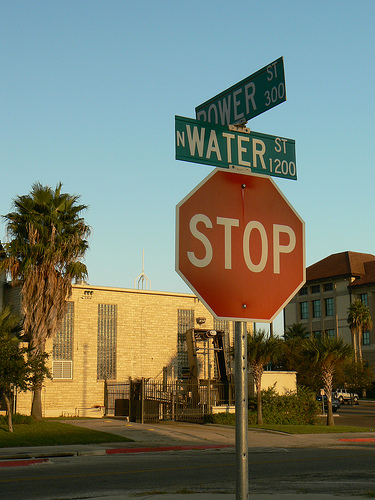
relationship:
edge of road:
[4, 490, 373, 500] [1, 439, 375, 495]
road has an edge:
[1, 439, 375, 495] [4, 490, 373, 500]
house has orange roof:
[279, 247, 374, 398] [304, 251, 374, 285]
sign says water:
[175, 115, 299, 182] [184, 123, 268, 168]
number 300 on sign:
[263, 82, 287, 108] [195, 55, 287, 128]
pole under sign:
[233, 322, 252, 499] [174, 166, 308, 322]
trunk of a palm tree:
[32, 365, 45, 421] [1, 180, 94, 421]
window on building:
[52, 299, 75, 381] [7, 281, 298, 417]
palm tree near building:
[1, 180, 94, 421] [7, 281, 298, 417]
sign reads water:
[175, 115, 299, 182] [184, 123, 268, 168]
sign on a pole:
[174, 166, 308, 322] [233, 322, 252, 499]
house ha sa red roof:
[279, 247, 374, 398] [304, 251, 374, 285]